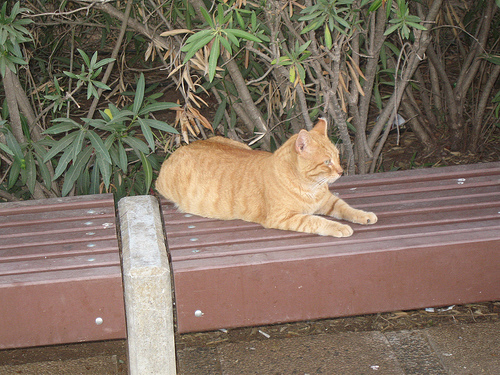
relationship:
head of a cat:
[273, 114, 346, 191] [146, 112, 382, 242]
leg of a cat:
[320, 195, 381, 227] [146, 112, 382, 242]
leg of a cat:
[300, 212, 357, 239] [155, 115, 382, 227]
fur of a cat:
[192, 170, 289, 194] [154, 116, 379, 238]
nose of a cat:
[337, 165, 347, 178] [154, 116, 379, 238]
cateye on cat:
[323, 158, 331, 165] [146, 112, 382, 242]